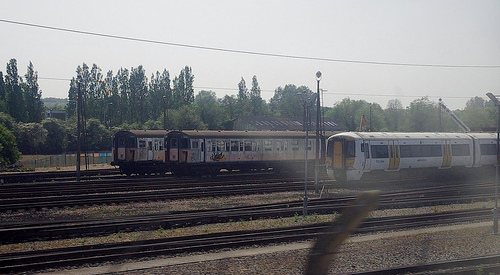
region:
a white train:
[327, 128, 498, 178]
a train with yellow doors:
[363, 131, 465, 168]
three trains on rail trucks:
[109, 127, 497, 185]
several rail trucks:
[3, 175, 490, 271]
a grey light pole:
[296, 101, 313, 213]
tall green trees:
[65, 62, 195, 119]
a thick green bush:
[0, 117, 115, 152]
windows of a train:
[197, 137, 302, 150]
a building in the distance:
[235, 112, 345, 127]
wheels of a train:
[118, 163, 169, 174]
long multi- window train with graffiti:
[166, 127, 356, 169]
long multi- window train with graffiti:
[111, 126, 166, 163]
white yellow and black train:
[327, 126, 499, 183]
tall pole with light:
[314, 66, 326, 192]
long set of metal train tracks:
[1, 203, 498, 270]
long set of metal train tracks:
[2, 186, 499, 241]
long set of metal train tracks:
[2, 172, 349, 217]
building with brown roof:
[221, 114, 348, 136]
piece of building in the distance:
[45, 107, 71, 124]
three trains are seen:
[80, 116, 402, 191]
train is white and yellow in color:
[321, 128, 438, 176]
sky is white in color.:
[220, 16, 336, 38]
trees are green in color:
[102, 83, 240, 111]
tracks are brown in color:
[80, 176, 202, 258]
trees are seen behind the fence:
[11, 65, 335, 129]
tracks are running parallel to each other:
[18, 173, 135, 260]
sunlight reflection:
[306, 91, 456, 228]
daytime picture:
[53, 77, 423, 253]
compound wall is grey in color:
[33, 158, 81, 165]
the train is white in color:
[330, 132, 499, 184]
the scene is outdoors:
[7, 1, 495, 271]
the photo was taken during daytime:
[1, 2, 496, 270]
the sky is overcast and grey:
[1, 2, 498, 132]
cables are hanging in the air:
[3, 2, 498, 114]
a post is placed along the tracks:
[313, 72, 325, 197]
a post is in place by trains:
[74, 72, 84, 184]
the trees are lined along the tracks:
[3, 56, 498, 156]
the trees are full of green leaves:
[3, 55, 498, 147]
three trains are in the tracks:
[113, 122, 499, 190]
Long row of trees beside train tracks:
[3, 61, 498, 129]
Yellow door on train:
[330, 138, 355, 167]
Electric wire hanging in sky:
[0, 12, 497, 65]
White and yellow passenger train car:
[321, 133, 498, 181]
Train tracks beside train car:
[6, 188, 498, 262]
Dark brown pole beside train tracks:
[75, 71, 85, 184]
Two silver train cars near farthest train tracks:
[113, 123, 327, 178]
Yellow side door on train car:
[388, 142, 400, 174]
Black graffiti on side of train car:
[210, 151, 228, 162]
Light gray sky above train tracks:
[0, 0, 495, 97]